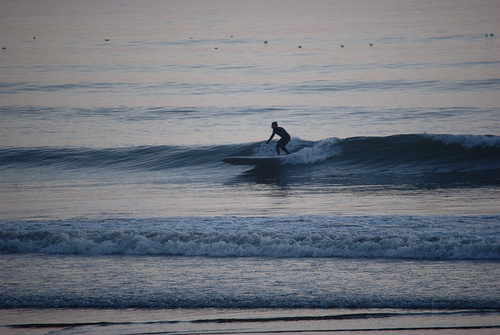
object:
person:
[268, 120, 289, 156]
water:
[0, 0, 499, 309]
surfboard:
[223, 156, 290, 167]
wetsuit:
[270, 129, 290, 152]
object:
[299, 45, 305, 48]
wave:
[0, 135, 500, 262]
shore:
[0, 306, 499, 332]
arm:
[267, 131, 278, 143]